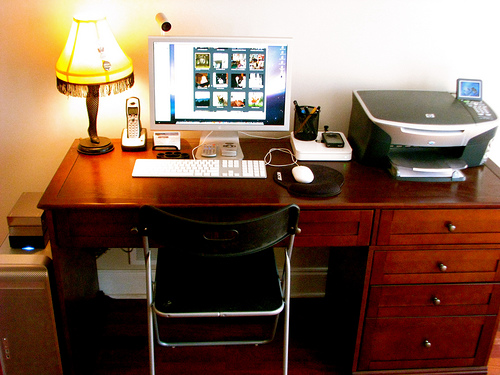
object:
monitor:
[148, 36, 292, 132]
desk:
[36, 136, 500, 374]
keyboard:
[132, 158, 267, 178]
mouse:
[291, 165, 314, 183]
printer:
[346, 78, 500, 182]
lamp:
[56, 11, 135, 156]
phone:
[121, 96, 147, 151]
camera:
[154, 12, 172, 33]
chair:
[138, 203, 302, 374]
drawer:
[360, 316, 485, 371]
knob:
[423, 339, 432, 348]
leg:
[84, 84, 102, 143]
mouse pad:
[273, 163, 346, 199]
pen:
[293, 100, 309, 132]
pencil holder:
[293, 105, 321, 141]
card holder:
[153, 131, 181, 151]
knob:
[430, 296, 441, 306]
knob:
[436, 262, 447, 272]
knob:
[445, 221, 456, 232]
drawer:
[376, 209, 499, 246]